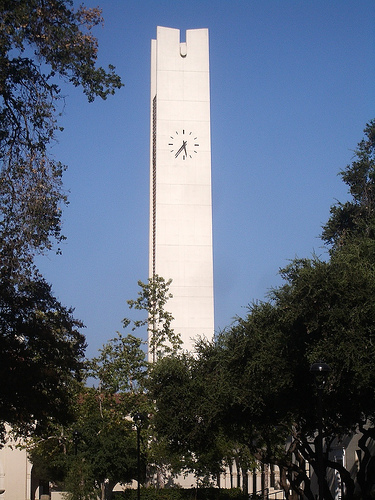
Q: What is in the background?
A: A tall clock tower.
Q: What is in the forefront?
A: Green trees.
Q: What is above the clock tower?
A: The blue sky.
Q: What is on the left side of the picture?
A: Green trees.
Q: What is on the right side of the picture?
A: Green trees.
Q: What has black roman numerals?
A: The clock.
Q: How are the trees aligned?
A: In a row.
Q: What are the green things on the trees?
A: Leaves.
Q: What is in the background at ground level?
A: Buildings.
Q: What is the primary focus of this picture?
A: Tower.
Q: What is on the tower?
A: Clock.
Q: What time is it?
A: 5:35.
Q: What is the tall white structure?
A: Clock tower.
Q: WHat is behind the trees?
A: Buildings.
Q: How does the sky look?
A: Clear and blue.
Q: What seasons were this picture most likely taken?
A: Spring or summer.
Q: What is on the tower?
A: A clock.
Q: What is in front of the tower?
A: Trees.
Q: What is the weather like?
A: Sunny and clear.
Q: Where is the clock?
A: On the tower.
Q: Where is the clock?
A: Tower.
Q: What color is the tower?
A: White.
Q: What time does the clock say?
A: It reads 5:35.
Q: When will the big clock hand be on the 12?
A: At 6:00.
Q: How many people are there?
A: NOne.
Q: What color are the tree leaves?
A: Green.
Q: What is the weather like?
A: Sunny and clear.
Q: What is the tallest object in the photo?
A: Clock tower.